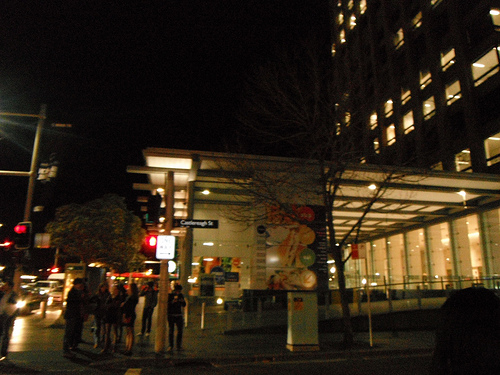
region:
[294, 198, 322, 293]
four vertical balloons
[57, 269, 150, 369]
A group of people standing on the street corner.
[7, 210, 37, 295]
A stop light that is red.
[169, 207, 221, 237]
a black and white street sign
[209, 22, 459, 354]
A tree with no leafs.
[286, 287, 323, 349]
a square electrical box.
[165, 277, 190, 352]
a woman holding a cup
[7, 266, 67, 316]
cars waiting at the stop light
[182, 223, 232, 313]
reflection of lights in the window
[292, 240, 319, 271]
a blown up green balloon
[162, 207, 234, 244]
sign is black and white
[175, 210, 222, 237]
sign is black and white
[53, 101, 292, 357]
people on a city street at night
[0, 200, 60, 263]
traffic lights at night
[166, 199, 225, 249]
street sign at night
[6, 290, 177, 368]
people standing at intersection at night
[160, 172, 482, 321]
lights on inside a lobby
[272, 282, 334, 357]
trash can on street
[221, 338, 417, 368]
curb is visible at night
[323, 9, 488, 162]
upper windows of building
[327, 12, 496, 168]
windows with lights on inside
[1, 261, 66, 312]
traffic in the distance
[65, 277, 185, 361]
this is a crowd of people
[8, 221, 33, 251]
this is a traffic light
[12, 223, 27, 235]
the traffic light is red in color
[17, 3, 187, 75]
this is the sky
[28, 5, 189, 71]
the sky is dark in color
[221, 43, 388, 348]
this is a tree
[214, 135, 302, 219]
the branches have no leaves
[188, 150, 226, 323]
this is a building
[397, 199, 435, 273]
the building is white in color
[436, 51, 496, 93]
these are several windows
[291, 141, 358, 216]
part of some tree branches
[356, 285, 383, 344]
part of a post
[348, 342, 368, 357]
edge of a road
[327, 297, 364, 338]
stem of a tree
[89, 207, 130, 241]
top of a tree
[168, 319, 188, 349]
part of a trouser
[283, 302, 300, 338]
edge of a container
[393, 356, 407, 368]
part of a road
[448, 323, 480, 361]
hair of a lady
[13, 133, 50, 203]
part of a tall post